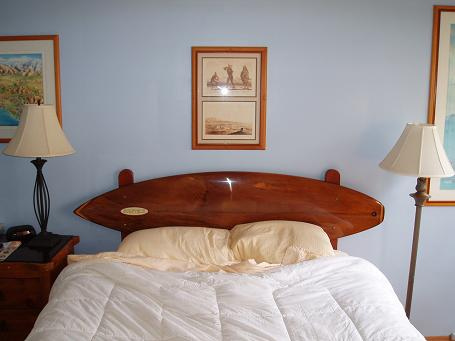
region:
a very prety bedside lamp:
[3, 101, 74, 250]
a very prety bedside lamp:
[379, 118, 451, 315]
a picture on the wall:
[184, 31, 271, 151]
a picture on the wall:
[0, 33, 64, 142]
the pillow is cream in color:
[121, 222, 232, 270]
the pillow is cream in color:
[230, 217, 336, 265]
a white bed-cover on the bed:
[26, 252, 421, 338]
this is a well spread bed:
[30, 221, 421, 339]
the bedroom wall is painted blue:
[2, 0, 453, 339]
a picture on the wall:
[422, 0, 453, 206]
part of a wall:
[308, 42, 360, 92]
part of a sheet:
[215, 282, 238, 311]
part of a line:
[274, 302, 290, 328]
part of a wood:
[220, 192, 247, 218]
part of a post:
[393, 222, 445, 266]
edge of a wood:
[370, 205, 388, 226]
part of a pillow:
[244, 229, 264, 247]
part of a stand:
[32, 188, 45, 209]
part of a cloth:
[194, 235, 221, 257]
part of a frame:
[217, 137, 243, 159]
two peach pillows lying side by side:
[117, 218, 332, 272]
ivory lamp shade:
[0, 98, 76, 159]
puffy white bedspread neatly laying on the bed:
[16, 251, 419, 339]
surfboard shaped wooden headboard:
[73, 155, 396, 245]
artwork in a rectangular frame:
[176, 43, 287, 158]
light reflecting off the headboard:
[215, 174, 248, 194]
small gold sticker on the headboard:
[120, 202, 152, 216]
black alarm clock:
[5, 222, 36, 239]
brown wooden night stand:
[0, 224, 74, 339]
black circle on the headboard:
[368, 206, 379, 218]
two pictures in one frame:
[184, 35, 275, 164]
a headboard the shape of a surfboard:
[70, 160, 387, 241]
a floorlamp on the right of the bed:
[370, 100, 451, 337]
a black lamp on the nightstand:
[7, 93, 95, 262]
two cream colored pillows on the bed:
[120, 198, 346, 274]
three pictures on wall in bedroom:
[6, 41, 453, 199]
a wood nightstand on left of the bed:
[4, 209, 84, 339]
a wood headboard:
[70, 148, 401, 274]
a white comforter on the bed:
[27, 249, 453, 336]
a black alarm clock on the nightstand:
[8, 220, 42, 257]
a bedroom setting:
[4, 2, 447, 337]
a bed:
[49, 159, 410, 337]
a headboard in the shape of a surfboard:
[72, 164, 386, 246]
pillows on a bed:
[113, 217, 336, 270]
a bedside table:
[0, 227, 98, 336]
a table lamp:
[1, 99, 76, 250]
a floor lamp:
[377, 113, 449, 321]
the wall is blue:
[286, 8, 377, 134]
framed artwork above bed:
[120, 32, 326, 321]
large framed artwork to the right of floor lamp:
[395, 2, 453, 307]